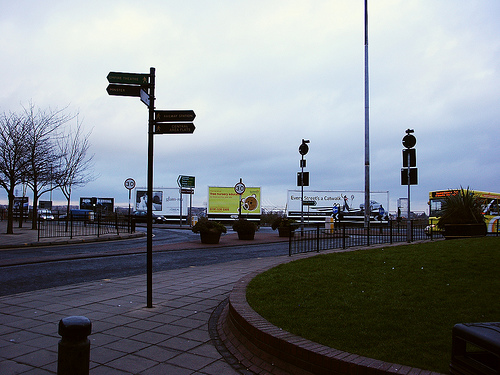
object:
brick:
[161, 350, 220, 372]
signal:
[398, 167, 420, 187]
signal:
[294, 169, 310, 188]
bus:
[422, 186, 500, 236]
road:
[0, 232, 446, 302]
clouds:
[0, 0, 499, 221]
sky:
[0, 0, 488, 215]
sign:
[122, 176, 138, 191]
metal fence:
[287, 217, 445, 258]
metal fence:
[34, 207, 137, 242]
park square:
[207, 230, 499, 374]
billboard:
[205, 183, 262, 215]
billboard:
[283, 188, 390, 220]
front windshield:
[428, 198, 449, 218]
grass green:
[244, 234, 499, 374]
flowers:
[189, 214, 229, 236]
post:
[361, 0, 375, 248]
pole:
[144, 63, 160, 307]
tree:
[54, 105, 104, 233]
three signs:
[295, 138, 311, 188]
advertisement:
[205, 184, 264, 217]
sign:
[105, 71, 152, 86]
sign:
[152, 109, 197, 124]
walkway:
[1, 234, 453, 374]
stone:
[100, 351, 168, 375]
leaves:
[31, 169, 55, 180]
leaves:
[14, 155, 27, 170]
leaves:
[1, 159, 10, 175]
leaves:
[8, 130, 26, 142]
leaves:
[32, 142, 48, 154]